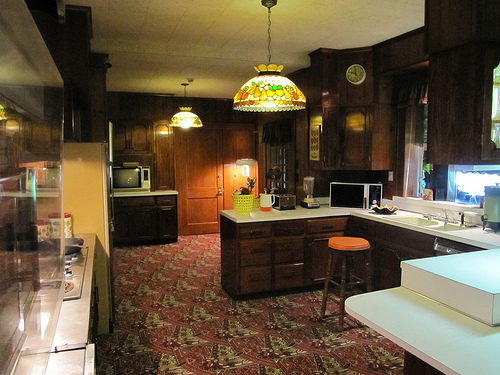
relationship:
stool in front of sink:
[315, 234, 376, 338] [377, 208, 467, 238]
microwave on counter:
[325, 178, 387, 212] [215, 199, 499, 374]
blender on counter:
[298, 174, 322, 211] [215, 199, 499, 374]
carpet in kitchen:
[99, 231, 413, 375] [1, 2, 497, 373]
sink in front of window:
[377, 208, 467, 238] [401, 85, 445, 202]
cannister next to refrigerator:
[58, 211, 77, 240] [60, 138, 115, 342]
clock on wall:
[344, 62, 369, 86] [251, 3, 499, 212]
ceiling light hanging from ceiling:
[230, 60, 311, 117] [56, 0, 432, 106]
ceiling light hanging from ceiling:
[164, 103, 205, 132] [56, 0, 432, 106]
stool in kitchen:
[315, 234, 376, 338] [1, 2, 497, 373]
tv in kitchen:
[109, 162, 153, 195] [1, 2, 497, 373]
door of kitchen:
[165, 118, 264, 240] [1, 2, 497, 373]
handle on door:
[216, 186, 226, 198] [165, 118, 264, 240]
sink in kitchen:
[377, 208, 467, 238] [1, 2, 497, 373]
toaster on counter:
[271, 193, 297, 213] [215, 199, 499, 374]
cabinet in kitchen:
[303, 233, 348, 287] [1, 2, 497, 373]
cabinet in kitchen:
[111, 207, 158, 249] [1, 2, 497, 373]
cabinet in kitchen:
[330, 105, 376, 171] [1, 2, 497, 373]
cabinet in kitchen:
[366, 239, 403, 289] [1, 2, 497, 373]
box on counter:
[394, 242, 499, 329] [215, 199, 499, 374]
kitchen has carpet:
[1, 2, 497, 373] [99, 231, 413, 375]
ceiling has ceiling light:
[56, 0, 432, 106] [230, 60, 311, 117]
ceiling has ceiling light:
[56, 0, 432, 106] [164, 103, 205, 132]